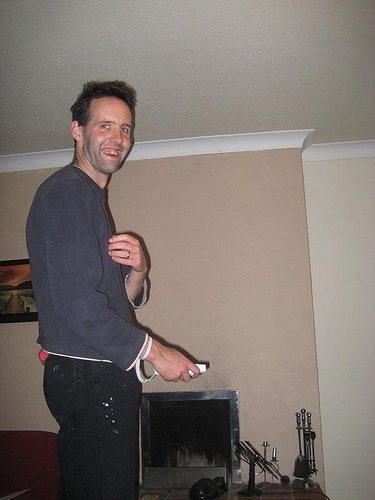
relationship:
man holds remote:
[24, 77, 202, 499] [150, 362, 209, 380]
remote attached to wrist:
[150, 362, 209, 380] [138, 332, 158, 368]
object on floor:
[188, 475, 232, 500] [136, 483, 328, 498]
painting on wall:
[1, 258, 38, 322] [4, 112, 327, 488]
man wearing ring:
[24, 77, 202, 499] [126, 251, 134, 262]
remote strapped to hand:
[150, 362, 209, 380] [141, 334, 203, 385]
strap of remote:
[134, 331, 156, 386] [150, 362, 209, 380]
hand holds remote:
[141, 334, 203, 385] [150, 362, 209, 380]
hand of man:
[141, 334, 203, 385] [24, 77, 202, 499]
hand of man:
[104, 230, 151, 280] [24, 77, 202, 499]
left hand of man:
[104, 230, 151, 280] [24, 77, 202, 499]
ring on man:
[126, 251, 134, 262] [24, 77, 202, 499]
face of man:
[68, 80, 139, 174] [24, 77, 202, 499]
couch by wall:
[0, 430, 63, 500] [4, 112, 327, 488]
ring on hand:
[126, 251, 134, 262] [104, 230, 151, 280]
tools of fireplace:
[226, 408, 327, 498] [135, 388, 244, 491]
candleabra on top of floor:
[257, 437, 282, 486] [136, 483, 328, 498]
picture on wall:
[1, 258, 38, 322] [4, 112, 327, 488]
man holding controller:
[24, 77, 202, 499] [150, 362, 209, 380]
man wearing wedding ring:
[24, 77, 202, 499] [126, 251, 134, 262]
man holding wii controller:
[24, 77, 202, 499] [150, 362, 209, 380]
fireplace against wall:
[135, 388, 244, 491] [4, 112, 327, 488]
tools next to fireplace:
[226, 408, 327, 498] [135, 388, 244, 491]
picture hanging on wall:
[1, 258, 38, 322] [4, 112, 327, 488]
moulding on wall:
[0, 127, 318, 174] [4, 112, 327, 488]